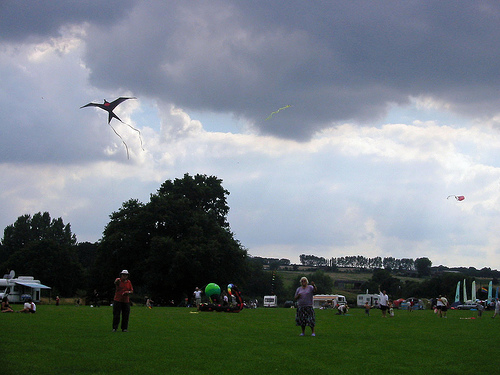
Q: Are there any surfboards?
A: No, there are no surfboards.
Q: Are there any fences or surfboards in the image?
A: No, there are no surfboards or fences.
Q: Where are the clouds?
A: The clouds are in the sky.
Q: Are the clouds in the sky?
A: Yes, the clouds are in the sky.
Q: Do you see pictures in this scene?
A: No, there are no pictures.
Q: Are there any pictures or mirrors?
A: No, there are no pictures or mirrors.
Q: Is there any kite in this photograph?
A: Yes, there is a kite.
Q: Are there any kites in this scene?
A: Yes, there is a kite.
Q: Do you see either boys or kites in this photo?
A: Yes, there is a kite.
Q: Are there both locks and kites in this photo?
A: No, there is a kite but no locks.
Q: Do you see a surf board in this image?
A: No, there are no surfboards.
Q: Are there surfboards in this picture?
A: No, there are no surfboards.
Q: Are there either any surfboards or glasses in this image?
A: No, there are no surfboards or glasses.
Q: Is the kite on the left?
A: Yes, the kite is on the left of the image.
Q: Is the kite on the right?
A: No, the kite is on the left of the image.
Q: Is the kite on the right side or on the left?
A: The kite is on the left of the image.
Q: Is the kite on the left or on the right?
A: The kite is on the left of the image.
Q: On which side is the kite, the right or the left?
A: The kite is on the left of the image.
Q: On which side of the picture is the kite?
A: The kite is on the left of the image.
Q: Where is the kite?
A: The kite is in the sky.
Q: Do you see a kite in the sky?
A: Yes, there is a kite in the sky.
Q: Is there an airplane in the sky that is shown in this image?
A: No, there is a kite in the sky.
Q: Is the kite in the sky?
A: Yes, the kite is in the sky.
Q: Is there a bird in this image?
A: Yes, there is a bird.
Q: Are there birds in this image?
A: Yes, there is a bird.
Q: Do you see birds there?
A: Yes, there is a bird.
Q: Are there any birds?
A: Yes, there is a bird.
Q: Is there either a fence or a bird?
A: Yes, there is a bird.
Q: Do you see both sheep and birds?
A: No, there is a bird but no sheep.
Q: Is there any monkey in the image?
A: No, there are no monkeys.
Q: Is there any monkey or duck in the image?
A: No, there are no monkeys or ducks.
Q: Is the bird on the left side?
A: Yes, the bird is on the left of the image.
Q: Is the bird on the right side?
A: No, the bird is on the left of the image.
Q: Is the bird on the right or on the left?
A: The bird is on the left of the image.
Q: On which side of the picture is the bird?
A: The bird is on the left of the image.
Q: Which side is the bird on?
A: The bird is on the left of the image.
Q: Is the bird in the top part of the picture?
A: Yes, the bird is in the top of the image.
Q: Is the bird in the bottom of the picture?
A: No, the bird is in the top of the image.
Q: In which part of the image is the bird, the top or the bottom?
A: The bird is in the top of the image.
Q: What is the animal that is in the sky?
A: The animal is a bird.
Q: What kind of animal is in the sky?
A: The animal is a bird.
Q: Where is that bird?
A: The bird is in the sky.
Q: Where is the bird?
A: The bird is in the sky.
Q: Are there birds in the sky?
A: Yes, there is a bird in the sky.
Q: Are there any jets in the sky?
A: No, there is a bird in the sky.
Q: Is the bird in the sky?
A: Yes, the bird is in the sky.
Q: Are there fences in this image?
A: No, there are no fences.